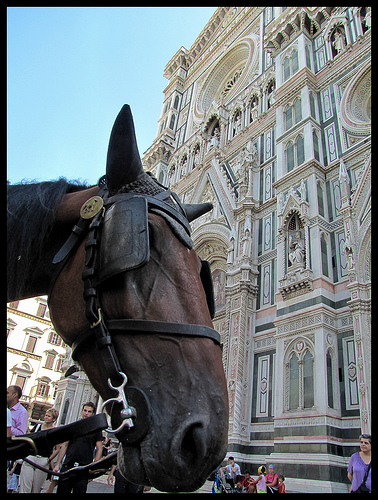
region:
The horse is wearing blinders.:
[84, 192, 170, 283]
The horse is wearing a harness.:
[19, 185, 242, 492]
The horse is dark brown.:
[3, 95, 228, 493]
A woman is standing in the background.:
[336, 428, 376, 498]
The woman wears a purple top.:
[335, 432, 376, 498]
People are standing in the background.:
[1, 375, 118, 492]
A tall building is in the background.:
[130, 7, 376, 497]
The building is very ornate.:
[147, 3, 372, 489]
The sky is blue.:
[3, 7, 226, 183]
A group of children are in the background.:
[208, 451, 294, 498]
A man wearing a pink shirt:
[6, 383, 27, 441]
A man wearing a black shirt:
[65, 403, 98, 468]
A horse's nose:
[100, 405, 251, 494]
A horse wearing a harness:
[15, 185, 246, 494]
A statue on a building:
[279, 218, 314, 289]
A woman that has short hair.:
[36, 402, 59, 428]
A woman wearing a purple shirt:
[342, 425, 373, 498]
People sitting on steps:
[197, 459, 283, 494]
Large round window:
[188, 30, 259, 125]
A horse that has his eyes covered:
[80, 193, 176, 315]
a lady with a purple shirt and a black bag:
[340, 429, 376, 495]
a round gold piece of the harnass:
[72, 189, 108, 221]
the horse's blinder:
[95, 193, 156, 279]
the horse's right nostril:
[167, 404, 230, 475]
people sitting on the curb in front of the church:
[212, 456, 297, 498]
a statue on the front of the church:
[272, 195, 313, 295]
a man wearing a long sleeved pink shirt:
[5, 383, 32, 448]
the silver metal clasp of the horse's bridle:
[84, 368, 138, 445]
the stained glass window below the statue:
[281, 334, 319, 416]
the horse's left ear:
[176, 186, 214, 229]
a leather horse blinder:
[90, 192, 161, 282]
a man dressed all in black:
[54, 391, 112, 493]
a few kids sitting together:
[235, 459, 291, 494]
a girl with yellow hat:
[251, 460, 275, 490]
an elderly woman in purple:
[345, 415, 375, 491]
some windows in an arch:
[277, 333, 326, 420]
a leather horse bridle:
[19, 169, 224, 452]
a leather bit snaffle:
[83, 365, 153, 442]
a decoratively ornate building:
[120, 68, 368, 418]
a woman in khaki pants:
[19, 401, 70, 483]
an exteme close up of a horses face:
[12, 130, 246, 486]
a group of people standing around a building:
[221, 458, 287, 497]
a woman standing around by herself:
[341, 436, 377, 490]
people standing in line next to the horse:
[5, 388, 127, 497]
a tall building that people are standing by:
[139, 7, 372, 495]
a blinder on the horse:
[94, 192, 148, 288]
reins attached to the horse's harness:
[16, 415, 119, 483]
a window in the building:
[279, 338, 317, 413]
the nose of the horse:
[169, 413, 227, 482]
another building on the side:
[12, 302, 59, 407]